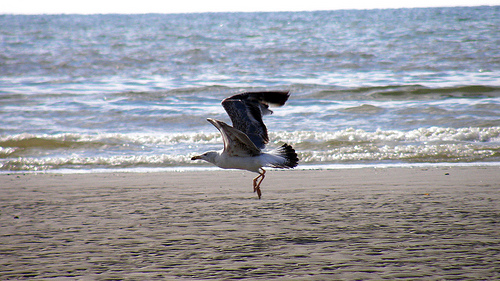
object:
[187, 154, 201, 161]
peck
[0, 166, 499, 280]
beach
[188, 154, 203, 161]
beak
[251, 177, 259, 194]
foot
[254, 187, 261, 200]
foot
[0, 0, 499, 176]
water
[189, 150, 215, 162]
head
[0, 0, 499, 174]
clear water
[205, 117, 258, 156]
wing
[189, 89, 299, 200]
bird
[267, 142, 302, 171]
tail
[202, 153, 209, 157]
eye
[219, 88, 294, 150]
wing